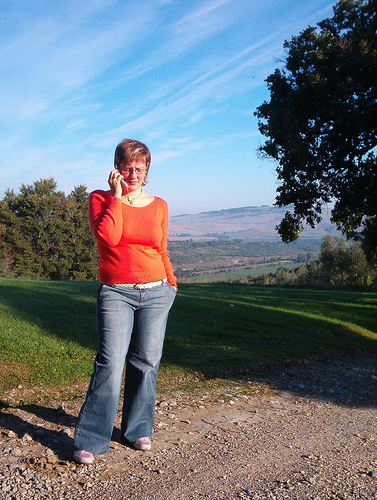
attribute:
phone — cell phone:
[103, 165, 159, 189]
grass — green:
[2, 275, 375, 411]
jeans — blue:
[72, 273, 175, 457]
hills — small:
[187, 204, 271, 262]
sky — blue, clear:
[64, 23, 196, 87]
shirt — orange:
[82, 189, 185, 291]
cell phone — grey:
[115, 174, 133, 191]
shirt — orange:
[86, 188, 181, 294]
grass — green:
[0, 285, 375, 403]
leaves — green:
[251, 3, 375, 267]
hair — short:
[104, 133, 157, 170]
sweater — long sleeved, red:
[90, 185, 176, 288]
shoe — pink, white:
[71, 448, 94, 465]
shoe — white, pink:
[130, 436, 153, 451]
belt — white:
[111, 279, 168, 289]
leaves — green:
[20, 210, 66, 244]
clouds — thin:
[7, 19, 263, 188]